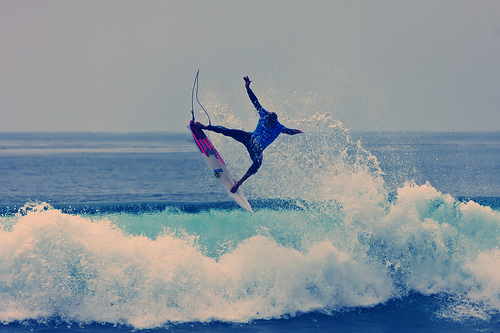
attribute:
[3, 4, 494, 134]
sky — clear, grey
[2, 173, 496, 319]
wave — large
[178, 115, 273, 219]
surfboard — neon pink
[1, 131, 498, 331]
ocean — blue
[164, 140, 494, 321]
water — elevated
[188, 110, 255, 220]
board — white, blue, pink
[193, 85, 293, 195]
wetsuit — blue, black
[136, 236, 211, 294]
splash — white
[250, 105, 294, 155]
shirt — blue